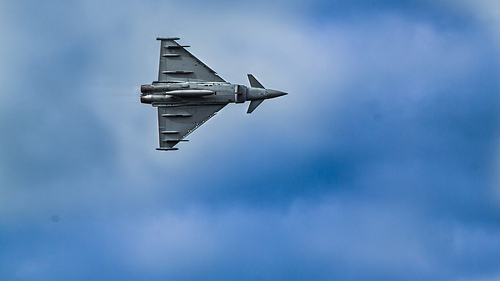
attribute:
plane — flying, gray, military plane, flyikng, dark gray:
[140, 35, 290, 157]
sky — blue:
[1, 1, 499, 279]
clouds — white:
[106, 18, 335, 166]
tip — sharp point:
[263, 85, 290, 103]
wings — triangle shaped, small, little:
[155, 35, 232, 153]